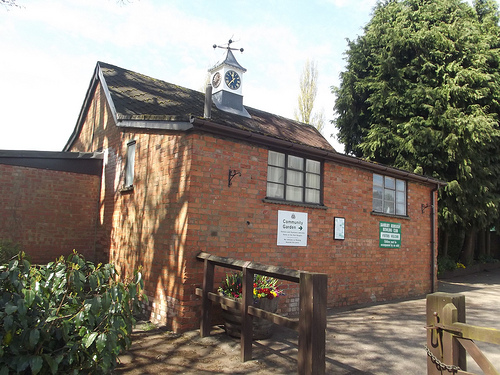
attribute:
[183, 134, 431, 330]
wall — red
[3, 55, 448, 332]
building — brick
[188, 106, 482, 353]
brick house — small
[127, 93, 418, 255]
building — red, brick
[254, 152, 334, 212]
window — small, wide, high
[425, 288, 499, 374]
gate — wooden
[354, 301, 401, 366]
dirt. — yard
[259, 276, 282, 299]
flowers — colorful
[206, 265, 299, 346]
box — flower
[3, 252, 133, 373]
shrub — wide, thick, bushy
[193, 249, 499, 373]
fence — wooden